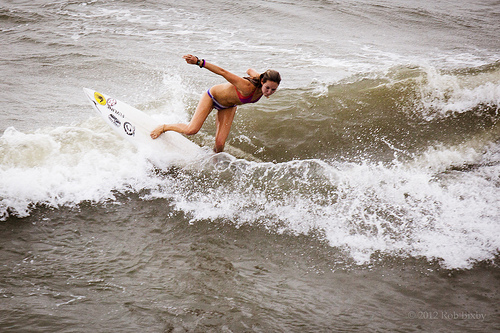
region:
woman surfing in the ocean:
[171, 49, 286, 156]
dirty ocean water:
[249, 283, 336, 327]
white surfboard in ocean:
[79, 82, 208, 185]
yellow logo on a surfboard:
[87, 91, 108, 108]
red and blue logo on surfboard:
[103, 94, 118, 106]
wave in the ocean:
[324, 58, 476, 153]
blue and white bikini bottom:
[203, 84, 233, 121]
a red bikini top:
[231, 56, 263, 110]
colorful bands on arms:
[177, 52, 211, 67]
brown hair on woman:
[244, 66, 278, 94]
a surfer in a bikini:
[145, 60, 288, 150]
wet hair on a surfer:
[250, 65, 280, 93]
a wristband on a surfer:
[193, 54, 207, 71]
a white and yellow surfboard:
[76, 77, 214, 175]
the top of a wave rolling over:
[404, 59, 498, 105]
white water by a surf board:
[13, 106, 197, 205]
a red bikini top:
[229, 81, 259, 113]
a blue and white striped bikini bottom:
[194, 88, 239, 113]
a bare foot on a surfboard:
[148, 120, 171, 140]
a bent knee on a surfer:
[177, 111, 208, 137]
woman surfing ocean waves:
[81, 54, 280, 155]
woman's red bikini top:
[228, 82, 264, 111]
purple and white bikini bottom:
[203, 87, 235, 119]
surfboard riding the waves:
[84, 87, 197, 165]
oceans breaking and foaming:
[290, 62, 477, 295]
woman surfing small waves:
[85, 35, 480, 256]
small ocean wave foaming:
[1, 108, 88, 326]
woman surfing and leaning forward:
[88, 56, 283, 164]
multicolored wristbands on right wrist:
[176, 54, 207, 71]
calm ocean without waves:
[4, 10, 482, 49]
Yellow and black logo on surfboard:
[93, 91, 105, 108]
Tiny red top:
[229, 82, 260, 110]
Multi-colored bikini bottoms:
[198, 87, 235, 114]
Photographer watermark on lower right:
[396, 303, 490, 328]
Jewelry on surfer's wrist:
[195, 50, 208, 73]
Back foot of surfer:
[148, 119, 175, 147]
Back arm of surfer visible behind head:
[241, 65, 263, 77]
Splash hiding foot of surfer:
[190, 144, 235, 191]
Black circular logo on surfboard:
[118, 114, 138, 140]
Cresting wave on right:
[368, 50, 499, 136]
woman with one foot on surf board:
[65, 38, 314, 233]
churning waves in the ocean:
[305, 28, 494, 287]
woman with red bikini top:
[159, 29, 284, 116]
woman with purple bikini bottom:
[143, 38, 296, 150]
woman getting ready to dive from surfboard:
[63, 30, 342, 210]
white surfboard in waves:
[74, 79, 210, 186]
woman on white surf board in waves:
[63, 32, 313, 212]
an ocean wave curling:
[335, 33, 497, 139]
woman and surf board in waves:
[21, 39, 464, 219]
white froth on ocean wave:
[265, 138, 499, 274]